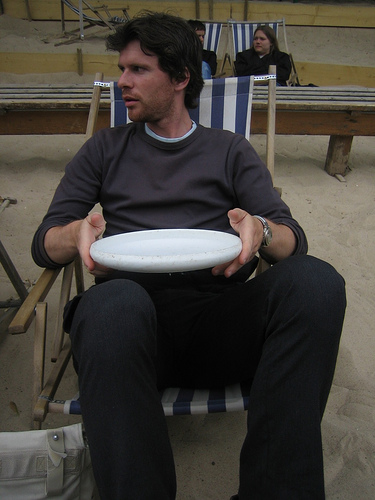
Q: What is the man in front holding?
A: A frisbee.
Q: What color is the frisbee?
A: White.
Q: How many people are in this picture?
A: Three.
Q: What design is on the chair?
A: Stripes.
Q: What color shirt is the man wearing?
A: Grey.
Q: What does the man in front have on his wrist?
A: A watch.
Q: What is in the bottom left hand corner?
A: A bag.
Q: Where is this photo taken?
A: The beach.